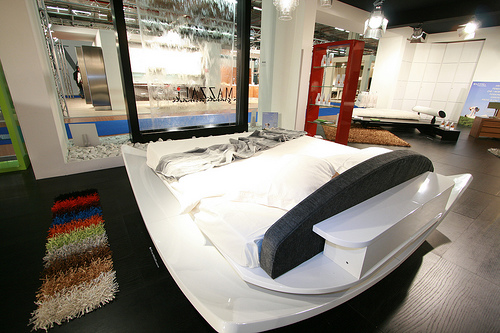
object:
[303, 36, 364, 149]
bookshelf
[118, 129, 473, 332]
bed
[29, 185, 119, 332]
carpet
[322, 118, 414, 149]
carpet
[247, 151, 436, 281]
headboard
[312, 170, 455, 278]
shelf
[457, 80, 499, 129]
poster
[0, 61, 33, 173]
bookshelf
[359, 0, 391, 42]
light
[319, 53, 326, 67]
bottle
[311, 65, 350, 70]
shelf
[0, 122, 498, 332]
ground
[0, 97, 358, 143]
floor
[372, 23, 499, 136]
wall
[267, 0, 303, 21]
light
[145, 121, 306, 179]
blanket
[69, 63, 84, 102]
person